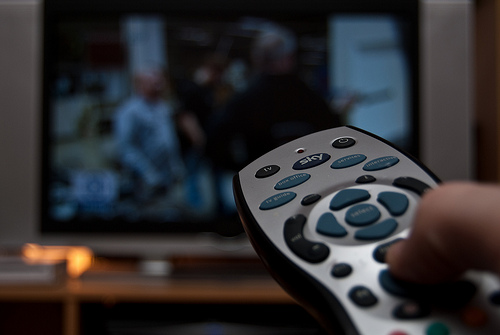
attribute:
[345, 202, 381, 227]
button — blue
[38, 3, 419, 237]
tv — black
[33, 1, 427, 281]
flatscreen tv — flat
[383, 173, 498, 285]
finger — big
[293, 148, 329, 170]
button — black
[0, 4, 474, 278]
tv — on, flat screened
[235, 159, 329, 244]
buttons — black 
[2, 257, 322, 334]
table — brown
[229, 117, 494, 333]
remote — silver, black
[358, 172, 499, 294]
thumb — bent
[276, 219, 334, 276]
buttons — black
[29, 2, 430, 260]
television — on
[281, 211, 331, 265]
button — black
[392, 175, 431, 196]
button — black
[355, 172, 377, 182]
button — black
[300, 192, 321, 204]
button — black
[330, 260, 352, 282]
button — black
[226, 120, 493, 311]
remote — silver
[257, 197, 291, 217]
button — blue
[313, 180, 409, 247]
button — black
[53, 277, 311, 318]
stand — wooden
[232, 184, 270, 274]
border — black